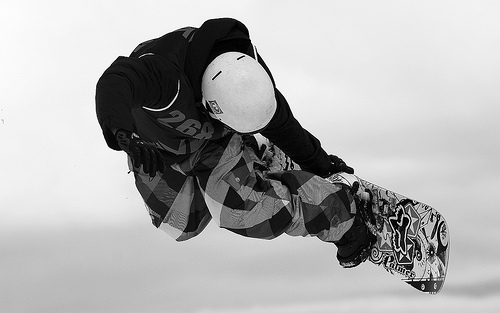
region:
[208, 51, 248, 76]
Two black spaces on the back of the helmet.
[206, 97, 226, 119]
Square sticker on the side of the helmet.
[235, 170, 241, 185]
Button on the pocket of the person's pants.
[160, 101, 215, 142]
Number on the front of the person's shirt.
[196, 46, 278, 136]
White helmet worn by the person.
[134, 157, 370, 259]
Snow pants worn by the person riding the board.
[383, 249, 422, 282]
The word Palmer on the board.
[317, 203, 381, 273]
The black boot slot on the board.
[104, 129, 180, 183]
The black glove on the person's left hand.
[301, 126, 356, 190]
The person's hand grabbing the board.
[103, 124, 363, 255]
some checkered snow pants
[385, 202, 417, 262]
the fox brand logo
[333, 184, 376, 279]
dark snow boots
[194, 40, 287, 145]
a hard, white ski helmet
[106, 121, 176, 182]
two toned padded gloves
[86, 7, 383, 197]
a dark hooded ski jacket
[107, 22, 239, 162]
a sports vest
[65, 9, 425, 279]
a man in winter sports clothes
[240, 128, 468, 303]
a busy patterned snowboard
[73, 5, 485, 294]
a snowboarder doing a trick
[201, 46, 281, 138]
white helmet on snowboarder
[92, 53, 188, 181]
right arm of snowboarder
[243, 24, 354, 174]
left arm of snowboarder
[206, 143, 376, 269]
left leg of snowboarder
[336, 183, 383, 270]
left foot of snowboarder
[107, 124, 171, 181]
right handoff snowboarder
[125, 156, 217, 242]
right upper leg of snowboarder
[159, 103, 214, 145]
268 on chest of snowboarder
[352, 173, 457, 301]
snowboard being used by person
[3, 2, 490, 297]
an outdoor scene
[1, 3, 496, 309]
the photo is clear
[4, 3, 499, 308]
the photo was taken during the day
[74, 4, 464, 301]
a man is in the photo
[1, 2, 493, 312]
the photo is colorless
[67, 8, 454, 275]
the man is wearing clothes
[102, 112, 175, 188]
the man has gloves on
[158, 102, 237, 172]
number 268 is seen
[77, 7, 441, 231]
the man has a dark hoodie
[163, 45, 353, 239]
the man is looking down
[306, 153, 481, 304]
the man has a skateboard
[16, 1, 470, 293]
black and white photo of a skateboarder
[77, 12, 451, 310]
skateboarder wearing a white helmet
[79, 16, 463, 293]
skateboarder wearing a black shirt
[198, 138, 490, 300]
skateboard with graffitti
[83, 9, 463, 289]
skateboarder looking and leaning downward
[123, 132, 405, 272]
skateboarder wearing checkered pants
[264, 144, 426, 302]
skateboarder wearing black shoes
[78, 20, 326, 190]
skateboarder wearing shirt that has 268 on it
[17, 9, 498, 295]
blurry gray background behind skateboarder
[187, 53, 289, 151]
logo in the side of skateboarder's helmet